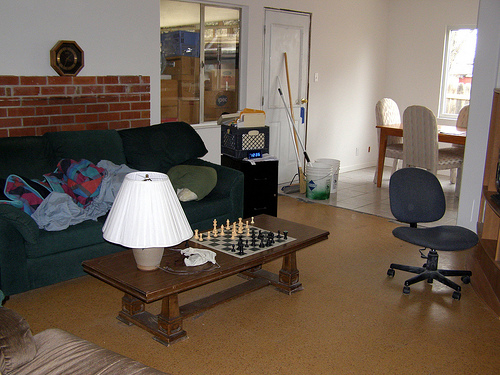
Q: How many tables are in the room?
A: Two.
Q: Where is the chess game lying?
A: On the coffee table.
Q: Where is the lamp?
A: Next to the chess game.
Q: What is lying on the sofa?
A: Clothes.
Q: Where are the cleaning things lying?
A: Near the white door.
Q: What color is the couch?
A: Dark green.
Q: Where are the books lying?
A: On the black crate.